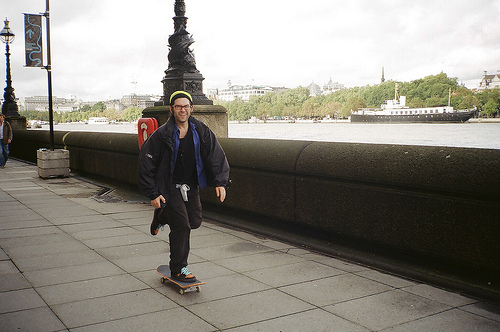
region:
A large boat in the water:
[346, 82, 486, 127]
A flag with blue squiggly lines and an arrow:
[21, 14, 44, 66]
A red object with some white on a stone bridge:
[136, 118, 159, 147]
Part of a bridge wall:
[232, 133, 499, 310]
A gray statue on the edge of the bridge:
[138, 0, 229, 132]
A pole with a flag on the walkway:
[23, 0, 73, 175]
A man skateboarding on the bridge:
[136, 92, 242, 304]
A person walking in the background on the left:
[0, 110, 13, 167]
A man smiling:
[164, 91, 209, 133]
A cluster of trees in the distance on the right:
[346, 69, 498, 122]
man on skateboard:
[100, 82, 260, 283]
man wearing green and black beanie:
[155, 72, 205, 150]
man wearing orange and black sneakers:
[147, 224, 231, 305]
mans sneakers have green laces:
[144, 245, 216, 290]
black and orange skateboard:
[151, 240, 258, 325]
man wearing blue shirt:
[165, 95, 237, 207]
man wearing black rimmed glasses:
[164, 87, 214, 138]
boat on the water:
[330, 87, 498, 148]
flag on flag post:
[17, 5, 81, 220]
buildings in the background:
[26, 82, 336, 120]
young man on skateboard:
[134, 70, 244, 301]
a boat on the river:
[342, 68, 482, 133]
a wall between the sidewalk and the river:
[247, 126, 498, 301]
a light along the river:
[0, 10, 30, 138]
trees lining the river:
[22, 70, 497, 125]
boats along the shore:
[247, 112, 362, 127]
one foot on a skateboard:
[126, 81, 237, 302]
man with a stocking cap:
[131, 77, 243, 309]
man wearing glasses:
[115, 83, 248, 313]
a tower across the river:
[372, 61, 390, 166]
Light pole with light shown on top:
[0, 12, 27, 132]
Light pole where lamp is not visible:
[143, 0, 227, 105]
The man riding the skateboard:
[136, 88, 237, 298]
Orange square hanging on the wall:
[134, 116, 159, 153]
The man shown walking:
[0, 114, 17, 166]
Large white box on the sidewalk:
[33, 144, 75, 180]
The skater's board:
[155, 256, 205, 298]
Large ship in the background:
[341, 79, 480, 125]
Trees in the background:
[18, 71, 498, 122]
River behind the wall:
[33, 110, 498, 147]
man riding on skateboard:
[103, 91, 227, 298]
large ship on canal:
[344, 73, 480, 129]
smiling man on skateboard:
[136, 85, 241, 155]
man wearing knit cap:
[161, 86, 206, 126]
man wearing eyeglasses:
[168, 94, 210, 125]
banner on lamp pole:
[17, 3, 57, 83]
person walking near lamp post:
[1, 104, 15, 176]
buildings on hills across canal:
[18, 72, 330, 125]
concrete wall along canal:
[23, 108, 493, 290]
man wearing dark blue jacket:
[126, 101, 254, 219]